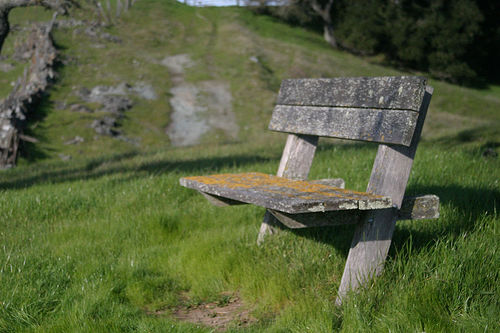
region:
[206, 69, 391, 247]
the bench is old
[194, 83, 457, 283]
the bench is antique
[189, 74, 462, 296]
the bench is in the field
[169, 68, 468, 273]
the bench is dirty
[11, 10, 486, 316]
The grass is growing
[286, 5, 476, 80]
the trees are in the back.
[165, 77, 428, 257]
the bench is wooden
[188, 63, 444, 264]
the bench is grey and red.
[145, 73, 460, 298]
the bench looks rusted.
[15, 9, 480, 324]
there is no one around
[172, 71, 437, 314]
Bench on the side of the hill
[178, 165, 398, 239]
bench seat has a yellow substance on it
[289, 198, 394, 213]
the side of the bench seat has paint scrapings on it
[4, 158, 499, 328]
the bench is surrounded by lush green grass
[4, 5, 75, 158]
a rock wall is at the bottom of the hill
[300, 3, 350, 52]
the trunk of a tree slightly blury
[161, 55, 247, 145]
rock formation with grass growing in areas of it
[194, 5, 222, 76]
ground that is indented to make it seem to be a bike trail of sorts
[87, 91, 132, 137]
small rock formation at the bottom of the hill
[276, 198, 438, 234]
bars that hold the seat of the bench in place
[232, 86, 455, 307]
old grey dirty bench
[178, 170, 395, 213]
Seat of a wooden bench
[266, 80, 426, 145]
Back rest of a wooden bench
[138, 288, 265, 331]
Dirt spot in the grass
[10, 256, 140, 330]
Grass in a field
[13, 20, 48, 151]
Rock formation on a hillside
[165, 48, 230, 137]
Rock path in the grass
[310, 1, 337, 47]
Tree trunk in a grass field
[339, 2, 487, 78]
Trees in a grass field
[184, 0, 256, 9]
Blue sky behind a field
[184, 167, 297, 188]
Moss growing on a wooden bench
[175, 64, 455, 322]
A small bench in the grass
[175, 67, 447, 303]
Grass growing around and under a bench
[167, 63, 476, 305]
A bench that appears to have missing legs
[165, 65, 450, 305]
A bench in the grass with something orange on it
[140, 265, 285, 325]
A bare spot in the grass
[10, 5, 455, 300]
Bench near a hill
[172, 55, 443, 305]
Bench that looks worn by weather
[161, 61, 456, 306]
Bench with braces underneath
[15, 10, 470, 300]
A blurry background in the distance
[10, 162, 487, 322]
Different shades of grass